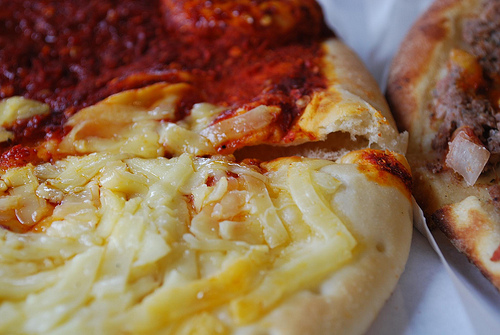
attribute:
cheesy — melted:
[51, 153, 292, 281]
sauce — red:
[0, 10, 271, 84]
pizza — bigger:
[0, 13, 385, 298]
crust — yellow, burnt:
[300, 163, 412, 320]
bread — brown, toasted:
[393, 21, 451, 118]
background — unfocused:
[5, 11, 275, 105]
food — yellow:
[0, 90, 403, 318]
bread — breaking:
[246, 100, 380, 168]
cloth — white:
[396, 199, 486, 328]